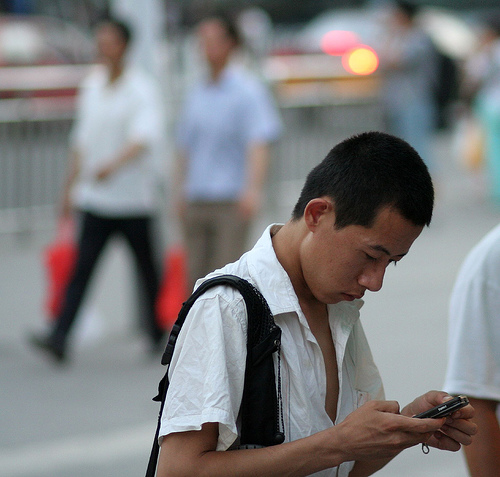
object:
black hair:
[288, 125, 438, 231]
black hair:
[197, 11, 242, 46]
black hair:
[93, 15, 131, 51]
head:
[290, 125, 435, 304]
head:
[86, 13, 134, 65]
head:
[190, 11, 242, 68]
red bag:
[42, 219, 79, 321]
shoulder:
[135, 239, 321, 417]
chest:
[291, 295, 348, 432]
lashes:
[393, 257, 399, 267]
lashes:
[364, 255, 377, 260]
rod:
[315, 89, 362, 117]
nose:
[357, 266, 386, 296]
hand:
[333, 398, 447, 463]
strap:
[149, 266, 288, 446]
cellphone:
[409, 394, 469, 425]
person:
[174, 10, 289, 301]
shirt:
[176, 63, 288, 207]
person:
[150, 129, 477, 474]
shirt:
[156, 220, 389, 475]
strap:
[420, 440, 430, 455]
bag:
[140, 273, 288, 476]